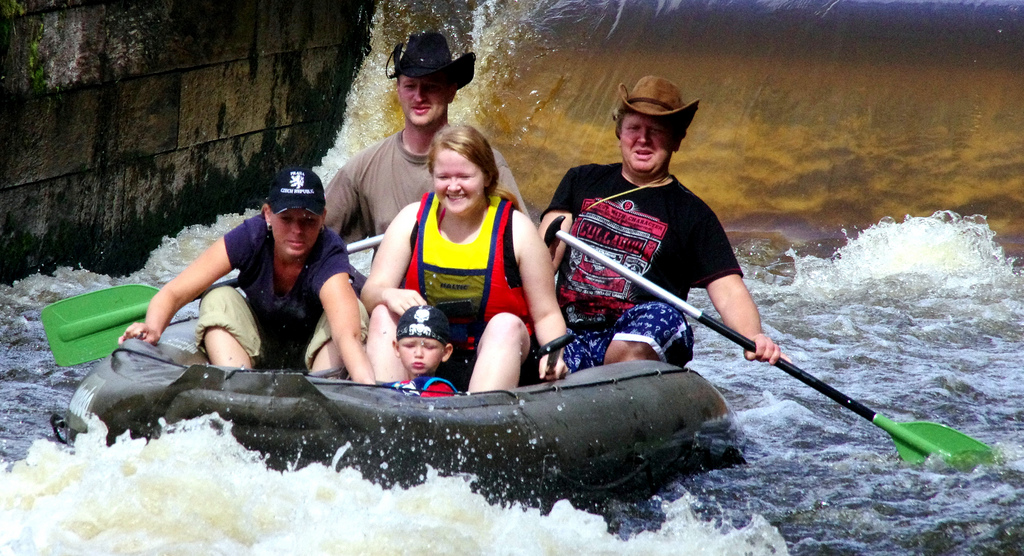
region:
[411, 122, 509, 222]
the head of a girl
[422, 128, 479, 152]
the hair of a girl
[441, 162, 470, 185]
the eyes of a girl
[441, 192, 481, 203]
the mouth of a girl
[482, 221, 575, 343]
the left arm of a girl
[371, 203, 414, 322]
the right arm of a girl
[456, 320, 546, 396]
the leg of a girl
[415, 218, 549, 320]
the life vest of a girl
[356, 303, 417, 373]
the right leg of a girl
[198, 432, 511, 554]
a bunch of white waves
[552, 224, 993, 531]
Paddle is in the water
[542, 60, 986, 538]
Man in black shirt is holding a paddle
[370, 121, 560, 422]
Smiling woman is holding her baby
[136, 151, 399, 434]
Person in blue hat has pants rolled up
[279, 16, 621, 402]
Man in an olive shirt is wearing a black hat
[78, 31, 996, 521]
4 people sitting in a large inflatable boat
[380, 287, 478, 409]
Little boy wearing his hat on backwards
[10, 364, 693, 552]
White rapids in front of the inflatable boat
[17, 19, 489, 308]
Block wall to the right of the people in the boat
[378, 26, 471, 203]
Man wearing cowboy hat.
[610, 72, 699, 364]
Man wearing brown cowboy hat.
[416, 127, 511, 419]
Woman wearing yellow shirt.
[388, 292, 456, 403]
Small child wearing baseball cap.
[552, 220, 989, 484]
Oar with green tip.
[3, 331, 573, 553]
Raft hitting rough waters.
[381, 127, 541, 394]
Woman wearing red vest.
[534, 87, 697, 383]
Man in blue shorts.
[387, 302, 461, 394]
small boy in the raft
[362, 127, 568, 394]
blonde woman in yellow shirt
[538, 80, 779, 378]
man in brown cowboy hat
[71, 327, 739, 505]
black raft going down a river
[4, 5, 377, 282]
wall made of cement blocks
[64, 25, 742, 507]
people in black rubber raft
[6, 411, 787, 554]
white cap of rushing water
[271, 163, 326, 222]
white emblem on cap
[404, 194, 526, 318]
vest with yellow neck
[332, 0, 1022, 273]
wall of smooth water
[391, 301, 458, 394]
child with cap on head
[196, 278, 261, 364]
folded up pant leg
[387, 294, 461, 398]
Small child wearing his cap backwards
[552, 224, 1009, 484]
Oar in the man's hand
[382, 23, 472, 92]
Black cowboy hat on man's head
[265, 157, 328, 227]
Baseball cap on the woman's head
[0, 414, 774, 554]
Choppy water in front of the boat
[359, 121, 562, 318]
Blonde-haired girl in the boat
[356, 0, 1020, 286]
Waterfall behind the people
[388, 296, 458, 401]
person riding in boat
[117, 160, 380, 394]
person riding in boat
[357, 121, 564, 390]
person riding in boat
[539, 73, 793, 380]
person riding in boat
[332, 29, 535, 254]
person riding in boat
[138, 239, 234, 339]
white colored human arm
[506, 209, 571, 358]
white colored human arm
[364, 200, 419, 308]
white colored human arm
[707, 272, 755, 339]
white colored human arm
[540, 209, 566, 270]
white colored human arm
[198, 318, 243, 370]
white colored human leg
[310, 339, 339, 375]
white colored human leg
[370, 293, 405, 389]
white colored human leg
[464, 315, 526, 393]
white colored human leg